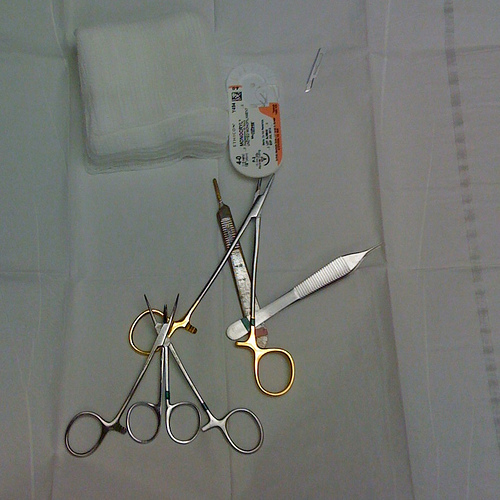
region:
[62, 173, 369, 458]
a set of surgical tools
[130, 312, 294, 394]
the handle is gold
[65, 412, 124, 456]
handle is dark metal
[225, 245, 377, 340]
the tweezers are silver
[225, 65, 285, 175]
white and orange tag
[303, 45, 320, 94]
a metal paper clip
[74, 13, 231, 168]
some pads of gauze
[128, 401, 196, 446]
handle of the scissors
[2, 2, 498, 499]
the cloth is white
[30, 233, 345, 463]
a group of scissors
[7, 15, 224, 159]
gauze on the left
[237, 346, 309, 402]
handle of the scissors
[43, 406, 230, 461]
handles of the scissors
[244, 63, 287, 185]
writing on the object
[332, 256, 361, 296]
the scissors are silver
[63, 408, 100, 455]
the handle is round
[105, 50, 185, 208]
the gauze is white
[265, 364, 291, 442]
part of a handle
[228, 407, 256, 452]
[art of a handle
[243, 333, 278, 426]
part f a handle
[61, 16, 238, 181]
folded stack of medical bandages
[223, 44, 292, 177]
orange and white container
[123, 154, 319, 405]
pair of gold handled medical scissors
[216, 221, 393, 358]
silver tweezers with green stripe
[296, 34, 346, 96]
small shiny silver blade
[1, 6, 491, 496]
white tissue background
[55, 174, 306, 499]
aerial view of 3 pairs of medical tools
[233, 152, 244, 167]
40 written in black on white package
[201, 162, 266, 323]
metal file laying flat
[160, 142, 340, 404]
small silver scissors on paper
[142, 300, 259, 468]
small silver scissors on paper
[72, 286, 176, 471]
small silver scissors on paper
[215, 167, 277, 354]
pointy tool on paper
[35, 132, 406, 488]
pointy tools on paper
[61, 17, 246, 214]
stack of white cloth bandages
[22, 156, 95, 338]
white paper under tools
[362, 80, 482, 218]
white paper under tools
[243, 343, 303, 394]
A handle on the scissors.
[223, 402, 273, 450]
A handle on the scissors.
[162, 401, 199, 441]
A handle on the scissors.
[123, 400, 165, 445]
A handle on the scissors.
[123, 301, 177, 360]
A handle on the scissors.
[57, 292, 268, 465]
A pair of scissors.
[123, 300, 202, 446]
A pair of scissors.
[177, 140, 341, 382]
A pair of scissors.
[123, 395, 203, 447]
Handle of a pair of scissors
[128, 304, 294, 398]
Handle of a pair of scissors